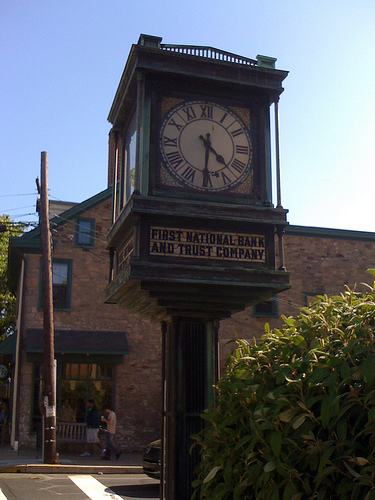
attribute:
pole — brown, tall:
[31, 149, 70, 463]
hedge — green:
[177, 285, 374, 477]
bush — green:
[179, 267, 373, 498]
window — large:
[37, 363, 117, 426]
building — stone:
[1, 172, 373, 455]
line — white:
[67, 472, 124, 499]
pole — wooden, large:
[18, 153, 59, 286]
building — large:
[21, 217, 367, 474]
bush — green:
[192, 282, 372, 493]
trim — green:
[6, 176, 107, 290]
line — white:
[53, 460, 132, 496]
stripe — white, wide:
[71, 467, 115, 499]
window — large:
[28, 340, 118, 458]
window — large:
[22, 322, 126, 447]